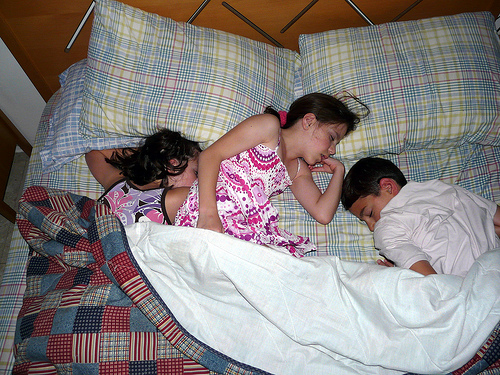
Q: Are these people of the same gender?
A: No, they are both male and female.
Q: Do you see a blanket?
A: Yes, there is a blanket.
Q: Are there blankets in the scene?
A: Yes, there is a blanket.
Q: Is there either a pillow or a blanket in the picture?
A: Yes, there is a blanket.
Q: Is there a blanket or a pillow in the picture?
A: Yes, there is a blanket.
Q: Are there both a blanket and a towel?
A: No, there is a blanket but no towels.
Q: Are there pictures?
A: No, there are no pictures.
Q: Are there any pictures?
A: No, there are no pictures.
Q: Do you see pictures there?
A: No, there are no pictures.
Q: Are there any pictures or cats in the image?
A: No, there are no pictures or cats.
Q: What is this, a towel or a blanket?
A: This is a blanket.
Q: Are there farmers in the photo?
A: No, there are no farmers.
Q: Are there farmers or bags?
A: No, there are no farmers or bags.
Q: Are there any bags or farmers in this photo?
A: No, there are no farmers or bags.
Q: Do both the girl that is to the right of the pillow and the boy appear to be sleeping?
A: Yes, both the girl and the boy are sleeping.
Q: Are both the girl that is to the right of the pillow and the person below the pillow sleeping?
A: Yes, both the girl and the boy are sleeping.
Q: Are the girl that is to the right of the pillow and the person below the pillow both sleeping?
A: Yes, both the girl and the boy are sleeping.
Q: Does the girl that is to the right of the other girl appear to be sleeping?
A: Yes, the girl is sleeping.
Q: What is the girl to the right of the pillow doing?
A: The girl is sleeping.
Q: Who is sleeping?
A: The girl is sleeping.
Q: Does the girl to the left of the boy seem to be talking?
A: No, the girl is sleeping.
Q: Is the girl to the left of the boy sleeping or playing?
A: The girl is sleeping.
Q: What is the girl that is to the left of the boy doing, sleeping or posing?
A: The girl is sleeping.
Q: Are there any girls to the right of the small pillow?
A: Yes, there is a girl to the right of the pillow.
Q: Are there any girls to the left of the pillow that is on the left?
A: No, the girl is to the right of the pillow.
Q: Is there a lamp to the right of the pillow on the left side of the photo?
A: No, there is a girl to the right of the pillow.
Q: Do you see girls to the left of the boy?
A: Yes, there is a girl to the left of the boy.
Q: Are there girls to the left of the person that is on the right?
A: Yes, there is a girl to the left of the boy.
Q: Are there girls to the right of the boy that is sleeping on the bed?
A: No, the girl is to the left of the boy.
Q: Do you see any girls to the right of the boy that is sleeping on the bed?
A: No, the girl is to the left of the boy.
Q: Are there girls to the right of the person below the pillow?
A: No, the girl is to the left of the boy.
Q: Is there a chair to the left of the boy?
A: No, there is a girl to the left of the boy.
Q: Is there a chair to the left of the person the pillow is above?
A: No, there is a girl to the left of the boy.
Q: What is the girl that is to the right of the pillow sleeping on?
A: The girl is sleeping on the bed.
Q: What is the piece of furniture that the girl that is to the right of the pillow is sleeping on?
A: The piece of furniture is a bed.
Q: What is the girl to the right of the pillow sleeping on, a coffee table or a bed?
A: The girl is sleeping on a bed.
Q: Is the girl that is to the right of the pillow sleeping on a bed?
A: Yes, the girl is sleeping on a bed.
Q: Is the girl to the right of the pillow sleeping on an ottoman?
A: No, the girl is sleeping on a bed.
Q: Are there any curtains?
A: No, there are no curtains.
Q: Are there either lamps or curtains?
A: No, there are no curtains or lamps.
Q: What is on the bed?
A: The sheets are on the bed.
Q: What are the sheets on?
A: The sheets are on the bed.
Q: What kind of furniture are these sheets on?
A: The sheets are on the bed.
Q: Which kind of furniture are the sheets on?
A: The sheets are on the bed.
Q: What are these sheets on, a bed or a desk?
A: The sheets are on a bed.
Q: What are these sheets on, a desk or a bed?
A: The sheets are on a bed.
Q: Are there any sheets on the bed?
A: Yes, there are sheets on the bed.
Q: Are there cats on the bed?
A: No, there are sheets on the bed.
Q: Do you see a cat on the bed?
A: No, there are sheets on the bed.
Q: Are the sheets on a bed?
A: Yes, the sheets are on a bed.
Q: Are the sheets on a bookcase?
A: No, the sheets are on a bed.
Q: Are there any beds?
A: Yes, there is a bed.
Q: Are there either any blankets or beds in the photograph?
A: Yes, there is a bed.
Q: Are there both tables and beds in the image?
A: No, there is a bed but no tables.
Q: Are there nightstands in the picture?
A: No, there are no nightstands.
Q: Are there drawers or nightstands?
A: No, there are no nightstands or drawers.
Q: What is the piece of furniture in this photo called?
A: The piece of furniture is a bed.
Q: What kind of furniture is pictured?
A: The furniture is a bed.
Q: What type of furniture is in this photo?
A: The furniture is a bed.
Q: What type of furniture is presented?
A: The furniture is a bed.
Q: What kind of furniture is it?
A: The piece of furniture is a bed.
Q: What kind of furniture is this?
A: This is a bed.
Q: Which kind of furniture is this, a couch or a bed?
A: This is a bed.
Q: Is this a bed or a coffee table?
A: This is a bed.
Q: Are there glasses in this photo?
A: No, there are no glasses.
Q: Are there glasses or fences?
A: No, there are no glasses or fences.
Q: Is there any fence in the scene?
A: No, there are no fences.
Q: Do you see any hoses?
A: No, there are no hoses.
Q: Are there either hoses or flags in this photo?
A: No, there are no hoses or flags.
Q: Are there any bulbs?
A: No, there are no bulbs.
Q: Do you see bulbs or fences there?
A: No, there are no bulbs or fences.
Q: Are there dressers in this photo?
A: No, there are no dressers.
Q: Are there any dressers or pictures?
A: No, there are no dressers or pictures.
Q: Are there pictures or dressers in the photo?
A: No, there are no dressers or pictures.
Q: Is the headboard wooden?
A: Yes, the headboard is wooden.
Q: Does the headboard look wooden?
A: Yes, the headboard is wooden.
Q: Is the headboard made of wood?
A: Yes, the headboard is made of wood.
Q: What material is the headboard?
A: The headboard is made of wood.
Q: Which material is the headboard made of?
A: The headboard is made of wood.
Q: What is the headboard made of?
A: The headboard is made of wood.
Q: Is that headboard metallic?
A: No, the headboard is wooden.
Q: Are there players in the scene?
A: No, there are no players.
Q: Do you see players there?
A: No, there are no players.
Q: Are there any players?
A: No, there are no players.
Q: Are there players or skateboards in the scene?
A: No, there are no players or skateboards.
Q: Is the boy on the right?
A: Yes, the boy is on the right of the image.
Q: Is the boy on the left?
A: No, the boy is on the right of the image.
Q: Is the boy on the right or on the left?
A: The boy is on the right of the image.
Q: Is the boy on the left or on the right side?
A: The boy is on the right of the image.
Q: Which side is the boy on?
A: The boy is on the right of the image.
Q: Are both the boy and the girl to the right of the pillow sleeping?
A: Yes, both the boy and the girl are sleeping.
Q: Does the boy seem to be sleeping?
A: Yes, the boy is sleeping.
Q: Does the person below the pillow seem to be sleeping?
A: Yes, the boy is sleeping.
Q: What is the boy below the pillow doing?
A: The boy is sleeping.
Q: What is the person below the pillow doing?
A: The boy is sleeping.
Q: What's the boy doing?
A: The boy is sleeping.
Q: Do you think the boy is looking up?
A: No, the boy is sleeping.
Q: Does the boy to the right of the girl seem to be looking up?
A: No, the boy is sleeping.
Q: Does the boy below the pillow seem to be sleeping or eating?
A: The boy is sleeping.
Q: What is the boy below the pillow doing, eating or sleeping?
A: The boy is sleeping.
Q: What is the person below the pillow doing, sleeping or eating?
A: The boy is sleeping.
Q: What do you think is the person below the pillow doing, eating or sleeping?
A: The boy is sleeping.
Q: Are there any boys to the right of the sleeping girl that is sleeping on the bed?
A: Yes, there is a boy to the right of the girl.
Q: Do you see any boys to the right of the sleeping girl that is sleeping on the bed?
A: Yes, there is a boy to the right of the girl.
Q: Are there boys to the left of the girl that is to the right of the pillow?
A: No, the boy is to the right of the girl.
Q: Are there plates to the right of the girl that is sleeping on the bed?
A: No, there is a boy to the right of the girl.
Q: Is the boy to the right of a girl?
A: Yes, the boy is to the right of a girl.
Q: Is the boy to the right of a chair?
A: No, the boy is to the right of a girl.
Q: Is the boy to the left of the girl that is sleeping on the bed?
A: No, the boy is to the right of the girl.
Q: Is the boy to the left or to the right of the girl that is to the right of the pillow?
A: The boy is to the right of the girl.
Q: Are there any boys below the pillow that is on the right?
A: Yes, there is a boy below the pillow.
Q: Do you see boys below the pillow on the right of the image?
A: Yes, there is a boy below the pillow.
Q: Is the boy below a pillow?
A: Yes, the boy is below a pillow.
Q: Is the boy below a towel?
A: No, the boy is below a pillow.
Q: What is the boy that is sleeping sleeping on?
A: The boy is sleeping on the bed.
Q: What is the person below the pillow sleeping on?
A: The boy is sleeping on the bed.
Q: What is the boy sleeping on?
A: The boy is sleeping on the bed.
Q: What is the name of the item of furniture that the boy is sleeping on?
A: The piece of furniture is a bed.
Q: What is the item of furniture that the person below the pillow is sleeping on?
A: The piece of furniture is a bed.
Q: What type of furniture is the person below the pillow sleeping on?
A: The boy is sleeping on the bed.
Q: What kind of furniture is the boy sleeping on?
A: The boy is sleeping on the bed.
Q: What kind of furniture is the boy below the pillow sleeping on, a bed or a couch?
A: The boy is sleeping on a bed.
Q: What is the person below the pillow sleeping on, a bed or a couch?
A: The boy is sleeping on a bed.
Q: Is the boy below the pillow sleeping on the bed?
A: Yes, the boy is sleeping on the bed.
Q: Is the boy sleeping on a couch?
A: No, the boy is sleeping on the bed.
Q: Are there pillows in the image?
A: Yes, there is a pillow.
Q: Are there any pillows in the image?
A: Yes, there is a pillow.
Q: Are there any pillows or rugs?
A: Yes, there is a pillow.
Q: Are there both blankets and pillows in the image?
A: Yes, there are both a pillow and a blanket.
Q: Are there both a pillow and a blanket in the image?
A: Yes, there are both a pillow and a blanket.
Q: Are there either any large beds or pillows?
A: Yes, there is a large pillow.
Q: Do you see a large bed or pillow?
A: Yes, there is a large pillow.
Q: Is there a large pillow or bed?
A: Yes, there is a large pillow.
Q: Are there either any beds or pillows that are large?
A: Yes, the pillow is large.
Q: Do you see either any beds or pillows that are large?
A: Yes, the pillow is large.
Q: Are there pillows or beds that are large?
A: Yes, the pillow is large.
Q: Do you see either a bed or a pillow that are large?
A: Yes, the pillow is large.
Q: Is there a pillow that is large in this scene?
A: Yes, there is a large pillow.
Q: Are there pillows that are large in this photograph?
A: Yes, there is a large pillow.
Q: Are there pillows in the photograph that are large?
A: Yes, there is a pillow that is large.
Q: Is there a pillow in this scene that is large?
A: Yes, there is a pillow that is large.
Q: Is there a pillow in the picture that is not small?
A: Yes, there is a large pillow.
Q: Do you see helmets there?
A: No, there are no helmets.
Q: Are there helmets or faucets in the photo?
A: No, there are no helmets or faucets.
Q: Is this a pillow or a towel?
A: This is a pillow.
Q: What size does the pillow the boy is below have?
A: The pillow has large size.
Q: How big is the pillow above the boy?
A: The pillow is large.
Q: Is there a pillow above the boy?
A: Yes, there is a pillow above the boy.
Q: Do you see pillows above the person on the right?
A: Yes, there is a pillow above the boy.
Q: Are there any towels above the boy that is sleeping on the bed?
A: No, there is a pillow above the boy.